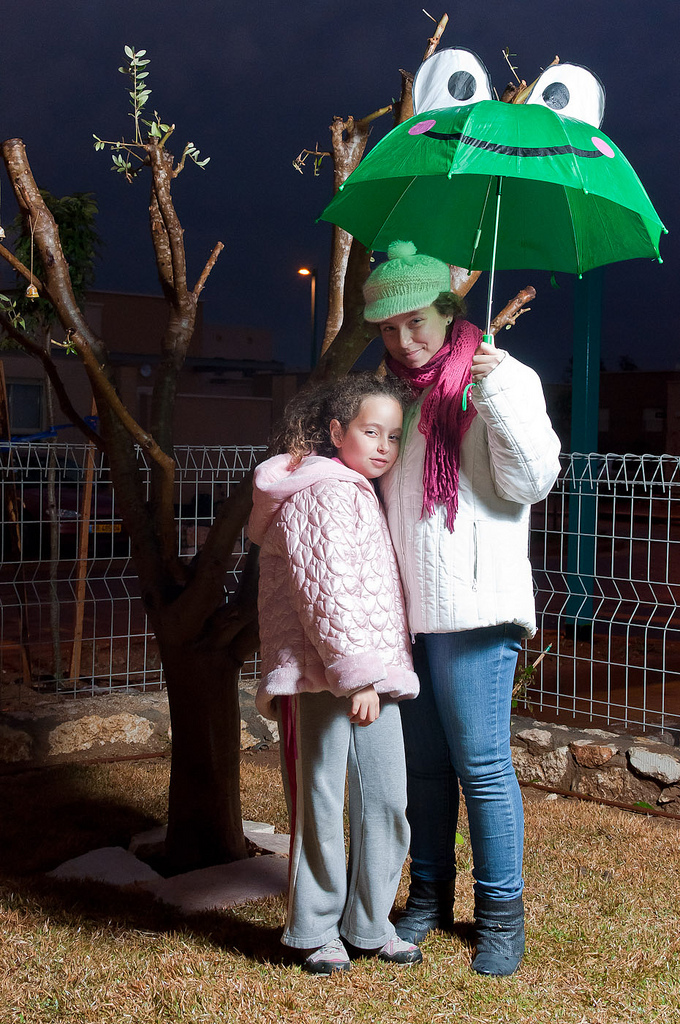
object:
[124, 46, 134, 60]
leaf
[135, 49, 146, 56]
leaf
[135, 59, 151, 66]
leaf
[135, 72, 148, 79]
leaf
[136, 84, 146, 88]
leaf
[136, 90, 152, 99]
leaf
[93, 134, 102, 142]
leaf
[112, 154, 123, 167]
leaf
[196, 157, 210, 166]
leaf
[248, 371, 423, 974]
girl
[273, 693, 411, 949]
pants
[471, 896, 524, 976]
boots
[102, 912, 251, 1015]
grass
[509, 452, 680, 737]
fence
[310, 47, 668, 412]
umbrella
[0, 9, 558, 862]
tree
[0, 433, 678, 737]
fence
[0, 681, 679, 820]
rock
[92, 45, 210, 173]
leaves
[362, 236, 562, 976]
lady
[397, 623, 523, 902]
jeans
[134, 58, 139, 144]
stem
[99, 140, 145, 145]
stem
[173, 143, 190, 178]
stem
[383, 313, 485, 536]
scarf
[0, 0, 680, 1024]
picture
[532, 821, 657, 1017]
grass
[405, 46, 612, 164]
frog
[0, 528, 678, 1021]
ground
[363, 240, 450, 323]
hat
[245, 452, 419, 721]
coat